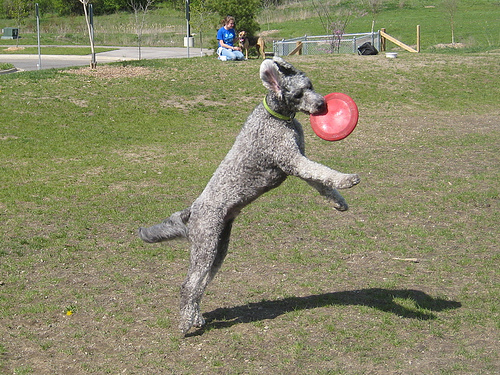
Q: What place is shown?
A: It is a park.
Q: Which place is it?
A: It is a park.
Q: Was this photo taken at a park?
A: Yes, it was taken in a park.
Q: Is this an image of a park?
A: Yes, it is showing a park.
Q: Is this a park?
A: Yes, it is a park.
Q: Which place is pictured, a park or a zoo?
A: It is a park.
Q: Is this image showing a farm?
A: No, the picture is showing a park.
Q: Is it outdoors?
A: Yes, it is outdoors.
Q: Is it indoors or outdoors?
A: It is outdoors.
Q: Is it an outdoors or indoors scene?
A: It is outdoors.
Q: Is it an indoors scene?
A: No, it is outdoors.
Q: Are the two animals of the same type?
A: Yes, all the animals are dogs.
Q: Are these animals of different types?
A: No, all the animals are dogs.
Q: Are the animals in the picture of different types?
A: No, all the animals are dogs.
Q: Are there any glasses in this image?
A: No, there are no glasses.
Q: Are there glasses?
A: No, there are no glasses.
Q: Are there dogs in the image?
A: Yes, there is a dog.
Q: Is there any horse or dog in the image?
A: Yes, there is a dog.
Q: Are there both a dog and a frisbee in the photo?
A: Yes, there are both a dog and a frisbee.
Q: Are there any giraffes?
A: No, there are no giraffes.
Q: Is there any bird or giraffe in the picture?
A: No, there are no giraffes or birds.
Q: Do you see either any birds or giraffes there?
A: No, there are no giraffes or birds.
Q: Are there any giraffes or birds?
A: No, there are no giraffes or birds.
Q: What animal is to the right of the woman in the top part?
A: The animal is a dog.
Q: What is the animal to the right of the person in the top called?
A: The animal is a dog.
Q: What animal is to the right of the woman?
A: The animal is a dog.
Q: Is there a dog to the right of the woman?
A: Yes, there is a dog to the right of the woman.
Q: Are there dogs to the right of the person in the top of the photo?
A: Yes, there is a dog to the right of the woman.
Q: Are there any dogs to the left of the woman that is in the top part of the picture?
A: No, the dog is to the right of the woman.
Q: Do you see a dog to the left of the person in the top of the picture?
A: No, the dog is to the right of the woman.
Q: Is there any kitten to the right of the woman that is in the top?
A: No, there is a dog to the right of the woman.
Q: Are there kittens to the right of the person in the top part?
A: No, there is a dog to the right of the woman.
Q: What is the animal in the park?
A: The animal is a dog.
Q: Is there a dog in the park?
A: Yes, there is a dog in the park.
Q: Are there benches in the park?
A: No, there is a dog in the park.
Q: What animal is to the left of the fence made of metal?
A: The animal is a dog.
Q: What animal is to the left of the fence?
A: The animal is a dog.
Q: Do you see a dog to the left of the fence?
A: Yes, there is a dog to the left of the fence.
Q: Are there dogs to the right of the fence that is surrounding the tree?
A: No, the dog is to the left of the fence.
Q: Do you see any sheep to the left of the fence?
A: No, there is a dog to the left of the fence.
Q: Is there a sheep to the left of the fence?
A: No, there is a dog to the left of the fence.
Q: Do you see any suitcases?
A: No, there are no suitcases.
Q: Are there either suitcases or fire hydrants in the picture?
A: No, there are no suitcases or fire hydrants.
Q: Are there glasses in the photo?
A: No, there are no glasses.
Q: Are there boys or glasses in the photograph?
A: No, there are no glasses or boys.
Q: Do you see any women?
A: Yes, there is a woman.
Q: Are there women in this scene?
A: Yes, there is a woman.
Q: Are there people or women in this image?
A: Yes, there is a woman.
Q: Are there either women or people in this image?
A: Yes, there is a woman.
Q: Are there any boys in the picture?
A: No, there are no boys.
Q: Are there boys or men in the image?
A: No, there are no boys or men.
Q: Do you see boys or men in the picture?
A: No, there are no boys or men.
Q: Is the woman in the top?
A: Yes, the woman is in the top of the image.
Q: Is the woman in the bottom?
A: No, the woman is in the top of the image.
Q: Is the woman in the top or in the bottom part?
A: The woman is in the top of the image.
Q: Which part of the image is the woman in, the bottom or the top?
A: The woman is in the top of the image.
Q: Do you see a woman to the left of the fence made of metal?
A: Yes, there is a woman to the left of the fence.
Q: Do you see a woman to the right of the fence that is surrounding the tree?
A: No, the woman is to the left of the fence.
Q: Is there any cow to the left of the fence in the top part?
A: No, there is a woman to the left of the fence.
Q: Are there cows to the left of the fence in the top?
A: No, there is a woman to the left of the fence.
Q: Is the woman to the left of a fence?
A: Yes, the woman is to the left of a fence.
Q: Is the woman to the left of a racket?
A: No, the woman is to the left of a fence.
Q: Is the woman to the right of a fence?
A: No, the woman is to the left of a fence.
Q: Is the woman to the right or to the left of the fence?
A: The woman is to the left of the fence.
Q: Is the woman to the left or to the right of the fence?
A: The woman is to the left of the fence.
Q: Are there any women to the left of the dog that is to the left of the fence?
A: Yes, there is a woman to the left of the dog.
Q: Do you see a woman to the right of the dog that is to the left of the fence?
A: No, the woman is to the left of the dog.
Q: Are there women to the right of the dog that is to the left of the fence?
A: No, the woman is to the left of the dog.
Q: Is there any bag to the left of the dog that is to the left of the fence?
A: No, there is a woman to the left of the dog.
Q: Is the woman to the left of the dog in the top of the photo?
A: Yes, the woman is to the left of the dog.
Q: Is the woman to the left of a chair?
A: No, the woman is to the left of the dog.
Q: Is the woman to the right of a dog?
A: No, the woman is to the left of a dog.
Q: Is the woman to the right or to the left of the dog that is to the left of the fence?
A: The woman is to the left of the dog.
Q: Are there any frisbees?
A: Yes, there is a frisbee.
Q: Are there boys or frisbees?
A: Yes, there is a frisbee.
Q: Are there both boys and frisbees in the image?
A: No, there is a frisbee but no boys.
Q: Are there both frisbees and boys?
A: No, there is a frisbee but no boys.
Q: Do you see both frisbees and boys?
A: No, there is a frisbee but no boys.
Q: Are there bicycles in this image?
A: No, there are no bicycles.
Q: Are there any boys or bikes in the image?
A: No, there are no bikes or boys.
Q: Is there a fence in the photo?
A: Yes, there is a fence.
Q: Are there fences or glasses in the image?
A: Yes, there is a fence.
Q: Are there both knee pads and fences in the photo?
A: No, there is a fence but no knee pads.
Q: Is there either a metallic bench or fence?
A: Yes, there is a metal fence.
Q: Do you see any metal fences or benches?
A: Yes, there is a metal fence.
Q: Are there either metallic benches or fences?
A: Yes, there is a metal fence.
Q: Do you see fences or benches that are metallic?
A: Yes, the fence is metallic.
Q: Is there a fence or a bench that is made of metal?
A: Yes, the fence is made of metal.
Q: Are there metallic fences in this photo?
A: Yes, there is a metal fence.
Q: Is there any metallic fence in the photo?
A: Yes, there is a metal fence.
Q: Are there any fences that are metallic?
A: Yes, there is a metal fence.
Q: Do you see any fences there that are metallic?
A: Yes, there is a fence that is metallic.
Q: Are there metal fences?
A: Yes, there is a fence that is made of metal.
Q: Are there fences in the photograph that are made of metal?
A: Yes, there is a fence that is made of metal.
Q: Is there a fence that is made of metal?
A: Yes, there is a fence that is made of metal.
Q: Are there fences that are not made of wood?
A: Yes, there is a fence that is made of metal.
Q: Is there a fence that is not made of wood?
A: Yes, there is a fence that is made of metal.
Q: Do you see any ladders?
A: No, there are no ladders.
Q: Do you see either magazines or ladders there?
A: No, there are no ladders or magazines.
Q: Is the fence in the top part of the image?
A: Yes, the fence is in the top of the image.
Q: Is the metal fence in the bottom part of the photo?
A: No, the fence is in the top of the image.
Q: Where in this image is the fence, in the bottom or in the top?
A: The fence is in the top of the image.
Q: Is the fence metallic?
A: Yes, the fence is metallic.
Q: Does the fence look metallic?
A: Yes, the fence is metallic.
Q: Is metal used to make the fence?
A: Yes, the fence is made of metal.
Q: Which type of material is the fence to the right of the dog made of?
A: The fence is made of metal.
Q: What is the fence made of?
A: The fence is made of metal.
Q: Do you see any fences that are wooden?
A: No, there is a fence but it is metallic.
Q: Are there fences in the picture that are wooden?
A: No, there is a fence but it is metallic.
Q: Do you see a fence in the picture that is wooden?
A: No, there is a fence but it is metallic.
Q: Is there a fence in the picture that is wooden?
A: No, there is a fence but it is metallic.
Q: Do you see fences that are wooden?
A: No, there is a fence but it is metallic.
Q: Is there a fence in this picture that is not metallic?
A: No, there is a fence but it is metallic.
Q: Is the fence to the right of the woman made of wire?
A: No, the fence is made of metal.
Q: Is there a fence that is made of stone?
A: No, there is a fence but it is made of metal.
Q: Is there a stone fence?
A: No, there is a fence but it is made of metal.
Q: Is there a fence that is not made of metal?
A: No, there is a fence but it is made of metal.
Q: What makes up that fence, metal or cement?
A: The fence is made of metal.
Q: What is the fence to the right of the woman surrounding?
A: The fence is surrounding the tree.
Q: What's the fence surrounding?
A: The fence is surrounding the tree.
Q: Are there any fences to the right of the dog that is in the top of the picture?
A: Yes, there is a fence to the right of the dog.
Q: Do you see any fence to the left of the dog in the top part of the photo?
A: No, the fence is to the right of the dog.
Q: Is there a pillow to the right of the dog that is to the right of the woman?
A: No, there is a fence to the right of the dog.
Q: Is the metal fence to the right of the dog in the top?
A: Yes, the fence is to the right of the dog.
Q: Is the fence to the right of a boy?
A: No, the fence is to the right of the dog.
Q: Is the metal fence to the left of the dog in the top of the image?
A: No, the fence is to the right of the dog.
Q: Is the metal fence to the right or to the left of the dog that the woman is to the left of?
A: The fence is to the right of the dog.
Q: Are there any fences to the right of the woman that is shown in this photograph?
A: Yes, there is a fence to the right of the woman.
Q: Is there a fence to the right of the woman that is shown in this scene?
A: Yes, there is a fence to the right of the woman.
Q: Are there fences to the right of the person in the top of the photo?
A: Yes, there is a fence to the right of the woman.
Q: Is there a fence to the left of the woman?
A: No, the fence is to the right of the woman.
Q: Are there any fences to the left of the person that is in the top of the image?
A: No, the fence is to the right of the woman.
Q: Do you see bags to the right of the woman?
A: No, there is a fence to the right of the woman.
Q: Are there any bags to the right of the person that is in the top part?
A: No, there is a fence to the right of the woman.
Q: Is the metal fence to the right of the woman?
A: Yes, the fence is to the right of the woman.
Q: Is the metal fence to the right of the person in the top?
A: Yes, the fence is to the right of the woman.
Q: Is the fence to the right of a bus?
A: No, the fence is to the right of the woman.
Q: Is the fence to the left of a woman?
A: No, the fence is to the right of a woman.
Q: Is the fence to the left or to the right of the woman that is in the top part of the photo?
A: The fence is to the right of the woman.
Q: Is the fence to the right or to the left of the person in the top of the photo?
A: The fence is to the right of the woman.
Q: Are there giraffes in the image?
A: No, there are no giraffes.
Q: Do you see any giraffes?
A: No, there are no giraffes.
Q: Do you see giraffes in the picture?
A: No, there are no giraffes.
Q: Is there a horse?
A: No, there are no horses.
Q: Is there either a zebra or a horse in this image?
A: No, there are no horses or zebras.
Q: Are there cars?
A: No, there are no cars.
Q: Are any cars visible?
A: No, there are no cars.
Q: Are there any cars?
A: No, there are no cars.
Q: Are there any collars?
A: Yes, there is a collar.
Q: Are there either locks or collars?
A: Yes, there is a collar.